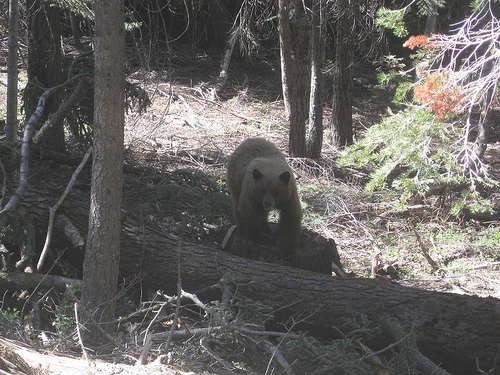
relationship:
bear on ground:
[227, 137, 303, 260] [0, 34, 497, 374]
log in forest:
[0, 180, 500, 375] [0, 0, 500, 316]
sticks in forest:
[122, 278, 383, 370] [2, 2, 496, 155]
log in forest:
[0, 180, 500, 375] [0, 0, 498, 375]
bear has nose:
[227, 137, 303, 260] [263, 203, 270, 211]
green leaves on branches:
[354, 107, 444, 195] [338, 65, 498, 212]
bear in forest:
[211, 129, 312, 241] [330, 59, 465, 184]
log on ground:
[124, 220, 499, 371] [2, 75, 498, 372]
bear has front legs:
[227, 137, 303, 260] [277, 198, 303, 258]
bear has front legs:
[227, 137, 303, 260] [239, 205, 269, 243]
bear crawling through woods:
[227, 137, 303, 260] [28, 59, 484, 359]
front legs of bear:
[277, 198, 303, 248] [227, 137, 303, 260]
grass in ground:
[123, 95, 498, 298] [0, 34, 497, 374]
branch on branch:
[334, 0, 500, 216] [334, 0, 500, 216]